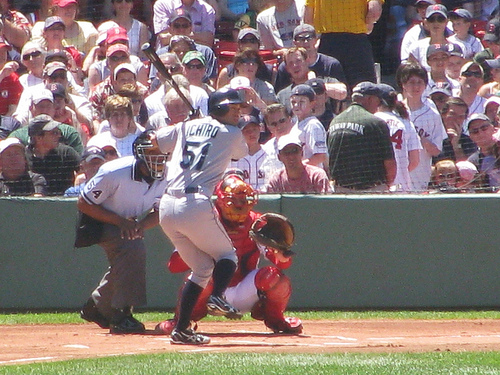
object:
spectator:
[22, 113, 83, 201]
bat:
[141, 41, 199, 117]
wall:
[0, 193, 500, 310]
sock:
[175, 278, 204, 335]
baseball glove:
[247, 212, 296, 251]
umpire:
[72, 130, 171, 337]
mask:
[136, 145, 171, 180]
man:
[12, 61, 94, 136]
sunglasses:
[48, 71, 68, 80]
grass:
[0, 309, 499, 324]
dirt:
[0, 319, 497, 365]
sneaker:
[169, 327, 212, 346]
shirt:
[325, 104, 395, 190]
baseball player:
[149, 85, 249, 346]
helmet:
[208, 87, 246, 115]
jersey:
[154, 115, 249, 194]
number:
[179, 140, 212, 171]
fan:
[326, 80, 397, 192]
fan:
[401, 63, 450, 190]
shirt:
[302, 0, 385, 35]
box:
[160, 331, 362, 353]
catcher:
[152, 167, 303, 336]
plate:
[153, 337, 171, 341]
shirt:
[6, 122, 84, 158]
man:
[88, 43, 151, 123]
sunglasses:
[107, 54, 130, 62]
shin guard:
[254, 266, 292, 322]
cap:
[105, 26, 129, 44]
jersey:
[399, 98, 448, 191]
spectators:
[262, 133, 334, 194]